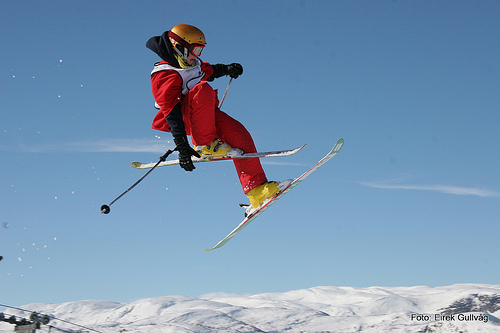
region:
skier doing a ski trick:
[105, 15, 342, 245]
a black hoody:
[116, 15, 344, 250]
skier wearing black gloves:
[108, 12, 388, 234]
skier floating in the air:
[121, 15, 351, 260]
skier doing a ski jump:
[105, 15, 355, 250]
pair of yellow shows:
[115, 6, 355, 241]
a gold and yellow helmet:
[110, 13, 377, 248]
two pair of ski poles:
[108, 13, 369, 258]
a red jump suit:
[103, 10, 358, 256]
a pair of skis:
[112, 20, 357, 250]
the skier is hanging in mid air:
[93, 5, 386, 262]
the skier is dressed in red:
[78, 4, 400, 268]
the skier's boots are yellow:
[197, 132, 290, 242]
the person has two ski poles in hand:
[102, 56, 244, 226]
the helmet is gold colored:
[146, 6, 219, 87]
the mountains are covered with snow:
[158, 270, 310, 327]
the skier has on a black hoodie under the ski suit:
[132, 25, 289, 182]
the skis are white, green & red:
[115, 139, 365, 274]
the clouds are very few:
[374, 173, 481, 219]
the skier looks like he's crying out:
[159, 14, 226, 74]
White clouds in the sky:
[24, 132, 498, 202]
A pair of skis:
[133, 139, 345, 251]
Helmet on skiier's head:
[165, 18, 207, 72]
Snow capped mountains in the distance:
[2, 283, 498, 328]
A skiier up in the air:
[97, 18, 348, 255]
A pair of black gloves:
[178, 61, 245, 175]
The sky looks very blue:
[3, 2, 498, 299]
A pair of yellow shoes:
[200, 134, 283, 209]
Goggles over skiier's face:
[188, 37, 206, 70]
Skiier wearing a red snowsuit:
[150, 23, 281, 194]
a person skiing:
[86, 5, 355, 214]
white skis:
[133, 129, 381, 237]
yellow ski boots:
[166, 128, 336, 228]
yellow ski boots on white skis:
[118, 91, 382, 261]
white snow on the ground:
[97, 262, 453, 329]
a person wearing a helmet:
[119, 15, 256, 108]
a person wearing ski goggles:
[139, 23, 232, 85]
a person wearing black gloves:
[128, 22, 258, 197]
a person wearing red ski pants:
[116, 22, 320, 199]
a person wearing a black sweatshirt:
[119, 17, 276, 164]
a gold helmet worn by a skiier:
[159, 18, 215, 73]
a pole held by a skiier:
[82, 171, 152, 220]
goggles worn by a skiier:
[185, 37, 205, 61]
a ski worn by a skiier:
[126, 138, 313, 174]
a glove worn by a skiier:
[156, 106, 205, 183]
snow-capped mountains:
[112, 264, 390, 323]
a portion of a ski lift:
[12, 303, 57, 330]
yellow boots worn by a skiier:
[236, 175, 285, 212]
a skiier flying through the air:
[41, 12, 383, 277]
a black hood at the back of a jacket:
[137, 25, 186, 77]